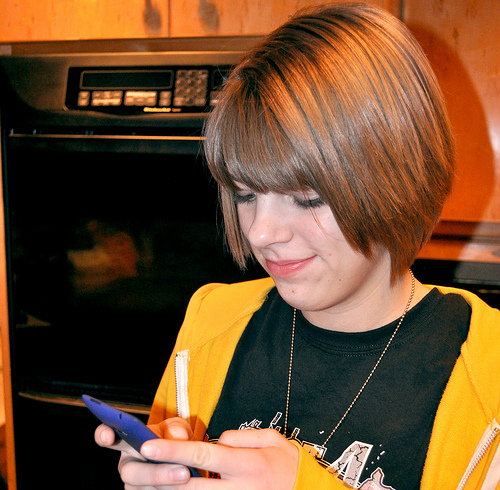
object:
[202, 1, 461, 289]
hair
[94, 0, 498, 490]
girl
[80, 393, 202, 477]
phone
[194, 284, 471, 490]
tshirt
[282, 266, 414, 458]
chain